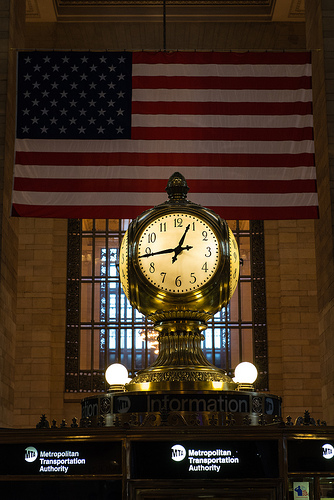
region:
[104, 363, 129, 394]
globe shaped light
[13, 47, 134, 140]
the stars on the USA flag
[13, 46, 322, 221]
the flag of the Unites States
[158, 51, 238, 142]
red and white stripes on the US flag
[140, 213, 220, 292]
a clock face with black numbers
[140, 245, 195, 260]
a minute hand on a clock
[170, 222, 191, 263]
an hour hand on a clock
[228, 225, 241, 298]
a face of a clock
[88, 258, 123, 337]
the bars on a window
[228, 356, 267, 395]
a globe shaped light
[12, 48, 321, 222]
a United States flag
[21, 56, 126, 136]
white stars on a blue background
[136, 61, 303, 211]
red and white stripes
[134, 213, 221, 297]
round face of a clock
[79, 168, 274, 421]
the clock in grand central station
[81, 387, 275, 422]
sign for the information counter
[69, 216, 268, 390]
tall windows with brasswork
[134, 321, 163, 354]
chandelier in the background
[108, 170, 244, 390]
large brass train clock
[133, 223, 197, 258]
hands of a clock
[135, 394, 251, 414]
white letters that say information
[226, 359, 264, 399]
white globe light with gold bottom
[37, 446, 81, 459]
white letters that say metropolitan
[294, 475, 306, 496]
blue red and white sticker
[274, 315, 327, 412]
brick work on a building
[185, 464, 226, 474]
white letters that say authority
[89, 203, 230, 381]
gold clock with black letters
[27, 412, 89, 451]
small metal decorative objects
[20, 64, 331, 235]
a large american flag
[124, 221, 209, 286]
black numbers on a clock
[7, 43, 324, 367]
gold clock with American flag in background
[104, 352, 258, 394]
two large globe lights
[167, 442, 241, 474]
white lettered Metropolitan Transportation Authority sign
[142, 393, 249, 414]
white lettered Information sign on black background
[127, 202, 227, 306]
round shiny golden clock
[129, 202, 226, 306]
round clock showing 12:44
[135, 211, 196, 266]
black hands on a pale lit clock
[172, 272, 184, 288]
black number 6 on a lit clock face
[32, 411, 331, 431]
metal design work on top of train station doors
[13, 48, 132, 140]
white stars on blue background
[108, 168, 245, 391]
an large illuminated clock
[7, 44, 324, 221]
a large American flag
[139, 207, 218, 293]
clock face reading 12:45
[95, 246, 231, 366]
a large outdoor window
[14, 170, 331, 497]
an information station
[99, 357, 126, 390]
a small round light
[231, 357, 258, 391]
a small round light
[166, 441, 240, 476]
logo name of organization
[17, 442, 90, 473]
logo name of organization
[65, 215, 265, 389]
a set of large window bars